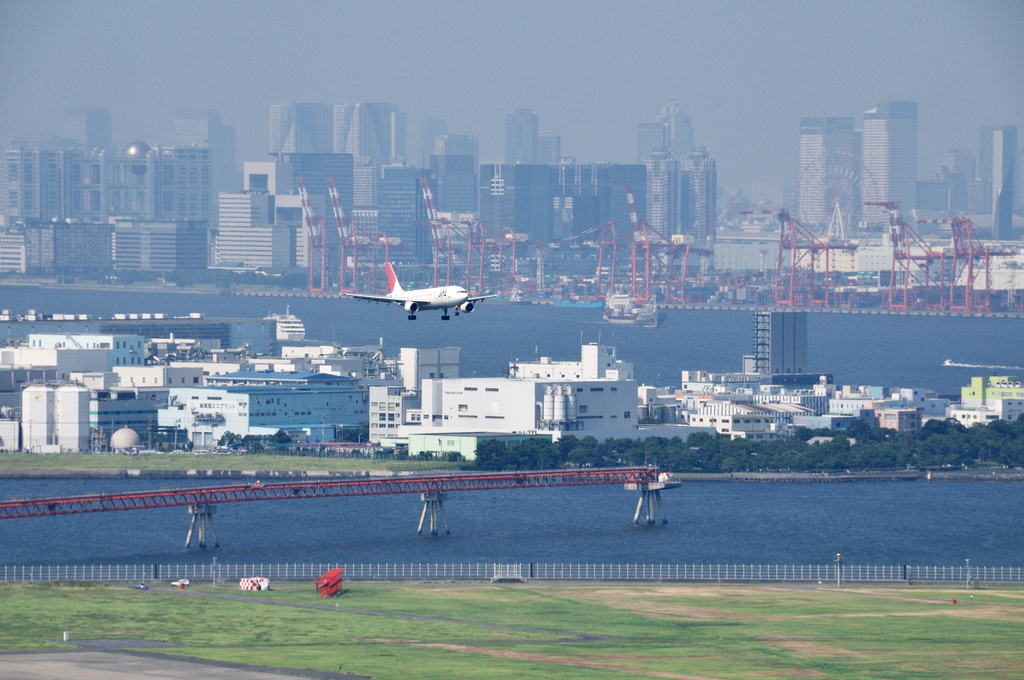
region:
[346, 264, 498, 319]
an airplane landing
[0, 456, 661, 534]
a bridge over a river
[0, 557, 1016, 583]
a fence near the river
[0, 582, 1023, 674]
a field near an airport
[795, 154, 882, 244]
a tall ferris wheel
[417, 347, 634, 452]
a white factory building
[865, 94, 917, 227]
a highrise sky scraper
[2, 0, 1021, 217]
a gray smoggy sky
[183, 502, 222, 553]
a concrete pillar in a river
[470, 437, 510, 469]
a bush on the shore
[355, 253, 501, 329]
A black and red airplane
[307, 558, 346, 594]
Small red tent in grass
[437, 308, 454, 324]
Black round plane tire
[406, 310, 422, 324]
Black round plane tire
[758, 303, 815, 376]
Gray skyscraper with windows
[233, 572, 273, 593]
Red and white checkered stand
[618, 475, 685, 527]
White stand holding bridge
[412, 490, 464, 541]
White stand holding bridge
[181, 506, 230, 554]
White stand holding bridge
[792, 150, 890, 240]
Red and white ferris wheel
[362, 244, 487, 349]
white plane landing at airport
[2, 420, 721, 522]
bridge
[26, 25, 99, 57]
white clouds in blue sky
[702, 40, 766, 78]
white clouds in blue sky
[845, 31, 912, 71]
white clouds in blue sky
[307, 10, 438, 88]
white clouds in blue sky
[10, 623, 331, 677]
The black paved road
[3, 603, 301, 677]
A black paved road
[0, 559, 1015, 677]
The green grassy lawn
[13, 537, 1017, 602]
The silver metal fence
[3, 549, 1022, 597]
A silver metal fence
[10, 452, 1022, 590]
The large body of water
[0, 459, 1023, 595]
A large body of water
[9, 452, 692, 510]
The red bridge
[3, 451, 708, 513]
A large red bridge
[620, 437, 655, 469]
green leaves on the tree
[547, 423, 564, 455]
green leaves on the tree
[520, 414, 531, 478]
green leaves on the tree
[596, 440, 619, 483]
green leaves on the tree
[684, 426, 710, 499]
green leaves on the tree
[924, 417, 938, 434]
green leaves on the tree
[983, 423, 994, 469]
green leaves on the tree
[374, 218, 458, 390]
a plane in the air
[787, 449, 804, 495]
green leaves on the tree